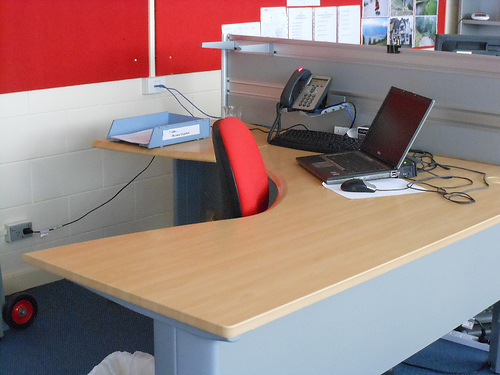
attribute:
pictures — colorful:
[363, 0, 438, 47]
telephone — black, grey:
[282, 63, 337, 113]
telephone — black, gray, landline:
[271, 64, 332, 115]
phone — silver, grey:
[267, 55, 344, 125]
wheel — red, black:
[3, 292, 36, 332]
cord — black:
[376, 148, 490, 205]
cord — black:
[250, 100, 357, 135]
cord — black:
[34, 156, 154, 233]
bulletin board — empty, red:
[9, 6, 126, 87]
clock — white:
[471, 9, 491, 21]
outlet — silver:
[142, 76, 168, 94]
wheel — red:
[2, 291, 42, 332]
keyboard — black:
[267, 126, 363, 154]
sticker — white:
[160, 121, 203, 141]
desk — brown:
[18, 112, 498, 373]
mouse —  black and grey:
[340, 180, 377, 192]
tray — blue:
[106, 110, 208, 151]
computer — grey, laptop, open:
[294, 84, 435, 185]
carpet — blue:
[3, 277, 495, 371]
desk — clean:
[127, 111, 499, 366]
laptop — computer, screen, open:
[297, 87, 434, 186]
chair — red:
[209, 112, 274, 218]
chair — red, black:
[208, 112, 273, 227]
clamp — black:
[380, 40, 401, 68]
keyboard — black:
[304, 155, 384, 180]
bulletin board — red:
[170, 2, 446, 46]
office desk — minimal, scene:
[21, 119, 499, 373]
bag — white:
[78, 348, 153, 373]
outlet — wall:
[5, 218, 34, 242]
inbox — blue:
[136, 76, 224, 158]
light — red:
[296, 65, 306, 73]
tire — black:
[2, 288, 41, 331]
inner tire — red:
[13, 298, 32, 322]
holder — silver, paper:
[99, 107, 217, 163]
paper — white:
[110, 120, 175, 147]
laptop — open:
[290, 80, 443, 192]